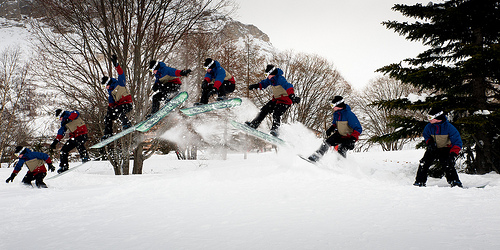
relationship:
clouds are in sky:
[262, 8, 314, 56] [0, 2, 458, 140]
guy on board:
[412, 110, 463, 189] [462, 183, 487, 189]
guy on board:
[307, 96, 363, 167] [296, 151, 350, 172]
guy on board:
[193, 57, 237, 105] [200, 81, 258, 111]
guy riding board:
[100, 54, 134, 140] [88, 120, 140, 150]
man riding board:
[48, 107, 90, 174] [45, 153, 101, 180]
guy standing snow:
[412, 110, 463, 189] [6, 97, 499, 248]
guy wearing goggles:
[247, 64, 302, 137] [422, 109, 449, 122]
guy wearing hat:
[412, 110, 463, 189] [430, 103, 444, 120]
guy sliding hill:
[412, 110, 463, 189] [1, 93, 481, 249]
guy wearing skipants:
[413, 110, 464, 187] [148, 84, 180, 116]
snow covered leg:
[0, 97, 499, 250] [303, 140, 330, 166]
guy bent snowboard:
[193, 53, 235, 104] [12, 178, 48, 197]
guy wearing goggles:
[412, 110, 463, 189] [424, 108, 443, 120]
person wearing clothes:
[6, 141, 53, 189] [11, 148, 50, 179]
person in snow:
[6, 141, 53, 189] [6, 97, 499, 248]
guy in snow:
[412, 110, 463, 189] [6, 97, 499, 248]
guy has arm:
[100, 54, 134, 140] [103, 40, 134, 90]